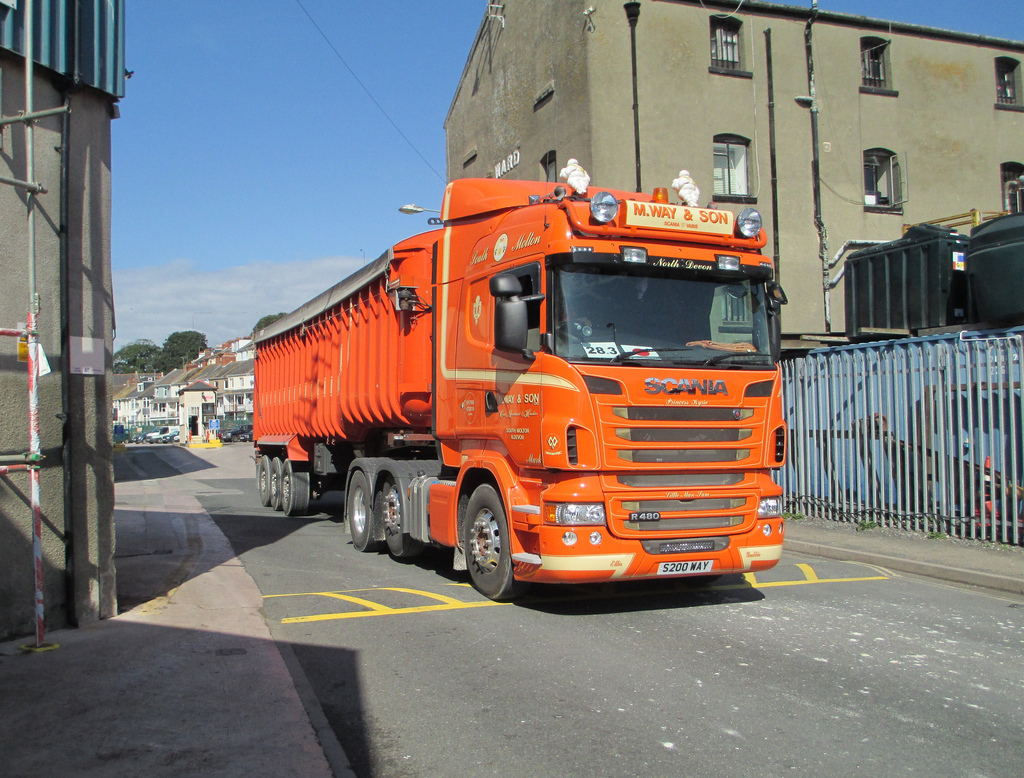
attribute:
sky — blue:
[211, 98, 288, 166]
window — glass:
[701, 15, 741, 64]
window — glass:
[700, 145, 752, 185]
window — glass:
[867, 36, 884, 91]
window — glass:
[867, 160, 896, 205]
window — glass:
[991, 60, 1020, 100]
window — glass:
[1004, 163, 1021, 201]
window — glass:
[881, 161, 902, 203]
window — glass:
[537, 157, 545, 189]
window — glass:
[230, 390, 240, 404]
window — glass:
[144, 397, 170, 417]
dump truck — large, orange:
[258, 167, 789, 607]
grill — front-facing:
[603, 397, 755, 540]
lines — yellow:
[261, 526, 894, 650]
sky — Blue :
[150, 33, 445, 234]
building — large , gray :
[438, 21, 999, 339]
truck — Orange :
[220, 173, 819, 610]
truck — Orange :
[258, 171, 770, 606]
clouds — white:
[100, 248, 377, 370]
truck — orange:
[195, 178, 725, 570]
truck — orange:
[200, 200, 814, 602]